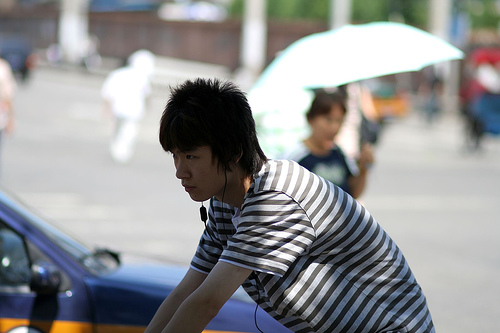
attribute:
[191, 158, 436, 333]
shirt — white, striped, dark, gray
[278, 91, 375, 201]
person — blurry, walking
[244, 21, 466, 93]
umbrella — open, white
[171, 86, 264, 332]
headphones — black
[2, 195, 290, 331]
car — yellow, blue, purple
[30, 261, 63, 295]
mirror — black, side view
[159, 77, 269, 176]
hair — black, spiky, short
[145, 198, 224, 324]
arm — bare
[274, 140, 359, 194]
shirt — blue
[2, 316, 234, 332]
line — orange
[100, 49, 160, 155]
person — walking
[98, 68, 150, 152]
suit — white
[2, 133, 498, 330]
street — gray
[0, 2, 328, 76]
fence — brown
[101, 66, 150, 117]
shirt — white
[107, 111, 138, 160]
pants — white